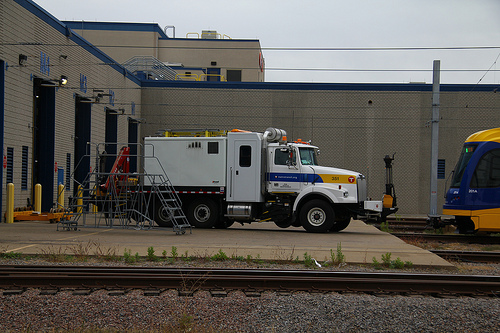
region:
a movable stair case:
[54, 140, 192, 232]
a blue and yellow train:
[441, 126, 498, 233]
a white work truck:
[142, 130, 369, 232]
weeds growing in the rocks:
[43, 246, 410, 270]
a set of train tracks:
[1, 262, 498, 295]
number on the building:
[38, 53, 50, 73]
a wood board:
[74, 286, 88, 297]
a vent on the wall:
[22, 145, 28, 189]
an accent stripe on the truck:
[265, 173, 355, 183]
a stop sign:
[0, 153, 7, 167]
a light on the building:
[53, 70, 73, 82]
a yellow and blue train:
[435, 125, 497, 236]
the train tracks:
[1, 264, 490, 289]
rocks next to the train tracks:
[14, 298, 495, 323]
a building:
[6, 10, 458, 187]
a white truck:
[141, 133, 361, 224]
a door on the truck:
[230, 136, 250, 196]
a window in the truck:
[276, 149, 291, 162]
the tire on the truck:
[297, 203, 332, 224]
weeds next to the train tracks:
[49, 243, 411, 265]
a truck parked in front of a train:
[118, 78, 495, 254]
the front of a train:
[428, 115, 498, 243]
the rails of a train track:
[6, 249, 493, 318]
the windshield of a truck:
[295, 144, 319, 164]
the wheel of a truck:
[296, 197, 337, 233]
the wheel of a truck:
[184, 197, 219, 230]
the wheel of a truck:
[148, 193, 183, 229]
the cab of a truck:
[268, 134, 371, 235]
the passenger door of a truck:
[268, 144, 300, 191]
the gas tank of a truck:
[223, 202, 255, 223]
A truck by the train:
[142, 127, 397, 224]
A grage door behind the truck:
[31, 77, 53, 212]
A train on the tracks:
[432, 127, 499, 235]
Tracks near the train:
[0, 263, 497, 296]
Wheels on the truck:
[152, 199, 328, 228]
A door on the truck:
[230, 139, 257, 201]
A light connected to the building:
[59, 74, 69, 85]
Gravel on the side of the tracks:
[2, 289, 497, 331]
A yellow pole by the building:
[6, 182, 14, 220]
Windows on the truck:
[276, 147, 313, 165]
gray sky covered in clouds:
[287, 8, 497, 44]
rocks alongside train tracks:
[251, 298, 386, 330]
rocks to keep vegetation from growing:
[199, 298, 299, 331]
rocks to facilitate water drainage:
[188, 298, 315, 331]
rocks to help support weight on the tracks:
[209, 300, 301, 331]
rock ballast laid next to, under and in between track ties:
[214, 301, 315, 330]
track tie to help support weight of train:
[148, 283, 225, 299]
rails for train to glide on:
[269, 277, 369, 289]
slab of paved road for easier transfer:
[313, 231, 374, 254]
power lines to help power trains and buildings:
[350, 42, 391, 58]